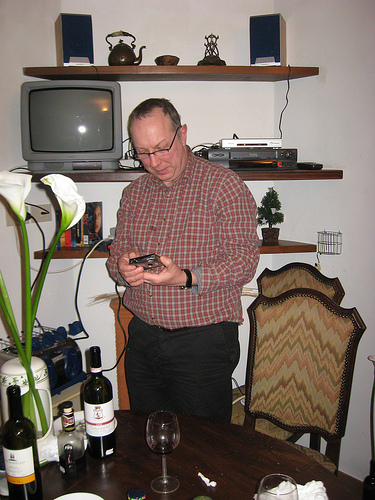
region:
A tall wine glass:
[144, 407, 189, 493]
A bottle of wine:
[82, 342, 119, 459]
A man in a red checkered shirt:
[94, 96, 262, 430]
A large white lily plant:
[0, 165, 86, 468]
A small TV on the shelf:
[19, 77, 128, 177]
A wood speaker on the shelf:
[244, 10, 291, 70]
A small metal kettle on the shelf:
[103, 26, 148, 66]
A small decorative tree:
[252, 186, 288, 243]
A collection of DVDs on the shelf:
[52, 197, 109, 248]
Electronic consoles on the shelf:
[194, 133, 302, 169]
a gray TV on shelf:
[19, 82, 126, 174]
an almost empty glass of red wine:
[145, 408, 181, 494]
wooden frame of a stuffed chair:
[245, 294, 366, 465]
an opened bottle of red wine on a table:
[85, 344, 117, 456]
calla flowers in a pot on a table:
[2, 170, 87, 463]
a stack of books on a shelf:
[57, 202, 104, 246]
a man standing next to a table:
[106, 96, 261, 434]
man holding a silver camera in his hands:
[116, 248, 179, 287]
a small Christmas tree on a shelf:
[254, 188, 284, 243]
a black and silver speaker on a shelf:
[250, 13, 287, 64]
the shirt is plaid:
[156, 292, 192, 320]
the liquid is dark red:
[156, 444, 169, 450]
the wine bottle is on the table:
[90, 381, 103, 396]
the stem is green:
[26, 302, 36, 351]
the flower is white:
[47, 175, 81, 223]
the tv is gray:
[28, 77, 64, 94]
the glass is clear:
[155, 422, 171, 434]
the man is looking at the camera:
[128, 251, 170, 277]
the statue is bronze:
[200, 30, 223, 63]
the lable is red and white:
[90, 411, 105, 431]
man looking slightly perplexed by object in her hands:
[105, 99, 257, 288]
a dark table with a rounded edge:
[2, 408, 371, 499]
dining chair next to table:
[241, 291, 365, 471]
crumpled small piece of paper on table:
[188, 467, 222, 491]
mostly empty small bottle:
[55, 398, 88, 481]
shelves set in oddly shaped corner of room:
[26, 2, 343, 266]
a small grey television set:
[16, 78, 122, 174]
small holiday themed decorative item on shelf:
[256, 185, 291, 252]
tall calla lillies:
[0, 165, 84, 434]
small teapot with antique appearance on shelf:
[103, 29, 146, 73]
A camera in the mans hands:
[127, 248, 169, 273]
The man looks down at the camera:
[104, 86, 260, 407]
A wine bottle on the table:
[83, 344, 124, 457]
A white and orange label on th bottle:
[1, 443, 37, 487]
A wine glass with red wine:
[143, 406, 186, 492]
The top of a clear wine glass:
[255, 467, 298, 498]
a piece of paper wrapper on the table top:
[196, 465, 219, 488]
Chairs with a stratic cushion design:
[254, 262, 356, 463]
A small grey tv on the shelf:
[15, 79, 123, 173]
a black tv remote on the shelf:
[298, 157, 323, 171]